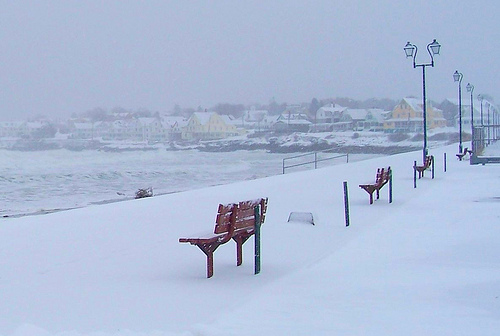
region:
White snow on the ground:
[56, 244, 160, 304]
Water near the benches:
[53, 155, 106, 193]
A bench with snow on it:
[180, 197, 269, 279]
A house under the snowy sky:
[388, 93, 443, 131]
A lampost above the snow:
[402, 40, 440, 166]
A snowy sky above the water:
[80, 46, 277, 71]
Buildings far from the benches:
[57, 114, 442, 137]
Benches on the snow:
[176, 153, 437, 288]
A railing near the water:
[283, 146, 355, 173]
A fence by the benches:
[475, 124, 499, 155]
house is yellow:
[187, 106, 232, 135]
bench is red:
[184, 204, 255, 241]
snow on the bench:
[187, 228, 210, 242]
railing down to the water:
[283, 140, 353, 165]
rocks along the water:
[231, 141, 275, 159]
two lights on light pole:
[403, 29, 446, 66]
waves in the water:
[126, 153, 159, 180]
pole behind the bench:
[244, 203, 270, 268]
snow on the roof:
[459, 90, 476, 104]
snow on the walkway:
[46, 229, 94, 289]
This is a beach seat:
[171, 182, 286, 290]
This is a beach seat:
[354, 152, 401, 218]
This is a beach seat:
[404, 145, 435, 192]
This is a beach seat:
[454, 138, 476, 167]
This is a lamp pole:
[400, 30, 442, 190]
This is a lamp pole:
[448, 60, 467, 169]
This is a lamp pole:
[464, 75, 478, 161]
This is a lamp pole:
[474, 86, 486, 156]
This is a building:
[309, 93, 356, 135]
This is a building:
[391, 86, 434, 133]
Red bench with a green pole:
[178, 190, 274, 284]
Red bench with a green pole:
[360, 158, 397, 214]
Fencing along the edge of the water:
[276, 133, 361, 171]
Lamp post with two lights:
[395, 26, 443, 162]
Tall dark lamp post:
[443, 65, 468, 155]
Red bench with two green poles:
[404, 151, 441, 186]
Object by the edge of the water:
[132, 180, 159, 205]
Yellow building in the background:
[176, 102, 246, 146]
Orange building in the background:
[375, 97, 448, 133]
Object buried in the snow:
[283, 203, 325, 242]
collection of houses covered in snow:
[0, 65, 499, 142]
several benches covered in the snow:
[181, 137, 485, 287]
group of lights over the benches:
[401, 39, 498, 169]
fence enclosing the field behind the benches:
[462, 117, 499, 169]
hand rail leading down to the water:
[273, 141, 362, 173]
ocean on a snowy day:
[1, 139, 398, 225]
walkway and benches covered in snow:
[0, 135, 480, 334]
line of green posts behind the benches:
[234, 146, 469, 281]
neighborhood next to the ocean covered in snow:
[0, 101, 495, 140]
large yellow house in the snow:
[379, 94, 453, 134]